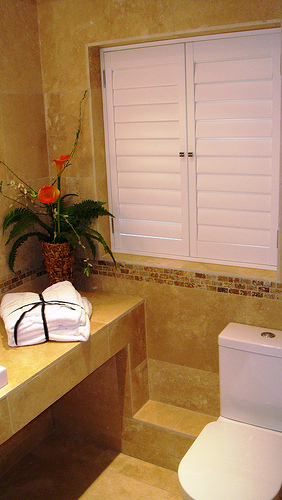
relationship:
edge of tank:
[211, 321, 237, 419] [204, 322, 279, 434]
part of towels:
[83, 332, 92, 344] [0, 280, 93, 347]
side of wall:
[78, 261, 273, 421] [38, 1, 281, 420]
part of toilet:
[174, 422, 230, 495] [153, 306, 281, 498]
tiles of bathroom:
[73, 245, 221, 437] [8, 7, 280, 494]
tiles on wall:
[99, 253, 272, 310] [45, 17, 92, 77]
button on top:
[259, 333, 273, 338] [217, 321, 271, 355]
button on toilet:
[259, 333, 273, 338] [174, 321, 279, 499]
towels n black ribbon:
[0, 280, 93, 347] [4, 292, 90, 347]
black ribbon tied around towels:
[4, 292, 90, 347] [4, 270, 91, 357]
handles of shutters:
[180, 149, 196, 159] [108, 45, 278, 264]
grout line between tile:
[106, 324, 111, 357] [108, 300, 147, 370]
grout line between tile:
[106, 324, 111, 357] [5, 323, 110, 433]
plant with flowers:
[1, 157, 117, 280] [37, 149, 81, 204]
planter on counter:
[28, 234, 83, 283] [2, 290, 146, 405]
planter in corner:
[28, 234, 83, 283] [20, 3, 76, 276]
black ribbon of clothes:
[4, 292, 90, 347] [0, 280, 93, 347]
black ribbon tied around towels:
[4, 291, 84, 344] [0, 280, 93, 347]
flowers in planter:
[4, 166, 111, 237] [40, 240, 76, 287]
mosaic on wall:
[1, 251, 278, 313] [2, 2, 280, 423]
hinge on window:
[98, 67, 108, 89] [84, 41, 280, 290]